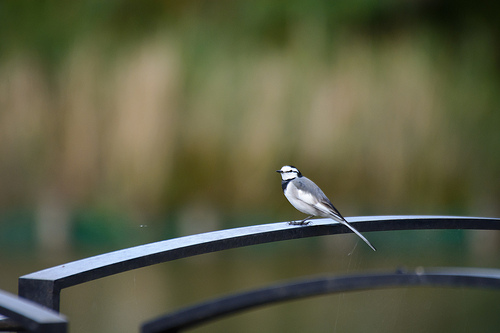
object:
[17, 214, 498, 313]
rail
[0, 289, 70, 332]
rail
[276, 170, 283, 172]
beak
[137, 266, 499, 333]
rail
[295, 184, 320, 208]
feathers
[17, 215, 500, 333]
railings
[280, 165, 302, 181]
head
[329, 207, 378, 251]
tail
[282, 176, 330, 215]
body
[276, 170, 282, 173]
peck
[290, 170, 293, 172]
eye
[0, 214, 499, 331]
metal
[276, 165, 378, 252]
bird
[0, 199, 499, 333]
piece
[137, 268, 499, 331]
fence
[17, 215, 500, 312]
fence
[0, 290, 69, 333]
fence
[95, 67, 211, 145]
background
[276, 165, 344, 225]
piece